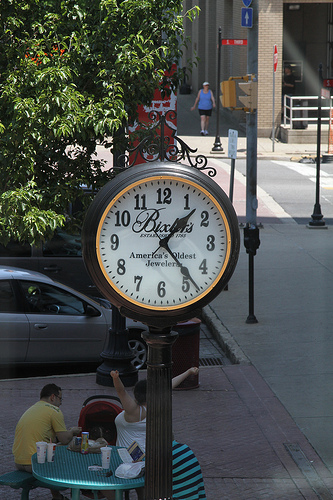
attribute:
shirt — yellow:
[12, 401, 71, 464]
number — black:
[156, 181, 171, 207]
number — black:
[204, 232, 219, 256]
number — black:
[175, 273, 192, 297]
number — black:
[134, 274, 147, 293]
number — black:
[102, 232, 120, 251]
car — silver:
[1, 273, 157, 362]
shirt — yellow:
[9, 401, 63, 459]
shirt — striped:
[170, 440, 205, 499]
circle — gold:
[92, 169, 232, 309]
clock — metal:
[116, 162, 226, 337]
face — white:
[98, 176, 226, 306]